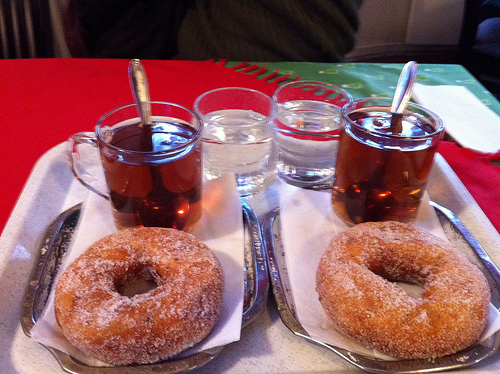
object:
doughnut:
[52, 223, 224, 367]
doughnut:
[312, 221, 490, 361]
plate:
[21, 188, 271, 374]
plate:
[259, 194, 500, 373]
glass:
[67, 101, 205, 239]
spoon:
[126, 56, 188, 231]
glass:
[331, 98, 446, 234]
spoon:
[342, 57, 418, 226]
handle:
[127, 56, 160, 127]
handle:
[388, 59, 420, 114]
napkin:
[410, 79, 499, 160]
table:
[2, 58, 500, 372]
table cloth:
[1, 58, 500, 240]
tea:
[97, 119, 204, 239]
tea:
[332, 107, 435, 229]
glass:
[192, 86, 276, 201]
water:
[193, 108, 273, 197]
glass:
[270, 79, 356, 192]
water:
[270, 97, 350, 189]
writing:
[251, 226, 269, 273]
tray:
[0, 126, 498, 373]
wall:
[354, 0, 476, 59]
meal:
[25, 92, 273, 373]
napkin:
[275, 180, 494, 363]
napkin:
[26, 169, 244, 357]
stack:
[412, 77, 499, 156]